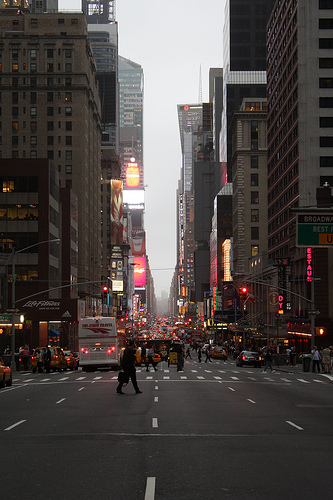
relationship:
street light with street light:
[238, 286, 247, 301] [242, 286, 248, 294]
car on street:
[233, 348, 263, 367] [3, 315, 328, 491]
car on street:
[206, 343, 228, 359] [3, 315, 328, 491]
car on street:
[29, 345, 66, 373] [3, 315, 328, 491]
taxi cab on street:
[134, 346, 161, 368] [3, 315, 328, 491]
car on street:
[189, 332, 204, 351] [3, 315, 328, 491]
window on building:
[120, 117, 135, 129] [117, 56, 144, 190]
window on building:
[123, 114, 135, 118] [117, 56, 144, 190]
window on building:
[116, 84, 120, 89] [117, 56, 144, 190]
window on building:
[116, 84, 142, 89] [117, 56, 144, 190]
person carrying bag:
[116, 340, 142, 395] [116, 371, 129, 383]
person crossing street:
[116, 340, 142, 395] [6, 340, 331, 498]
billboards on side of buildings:
[104, 178, 149, 292] [3, 13, 144, 369]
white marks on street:
[44, 372, 329, 384] [178, 323, 217, 499]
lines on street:
[2, 358, 332, 499] [3, 315, 328, 491]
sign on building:
[298, 246, 314, 281] [264, 0, 331, 325]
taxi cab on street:
[127, 342, 164, 369] [6, 340, 331, 498]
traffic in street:
[131, 316, 262, 366] [3, 315, 328, 491]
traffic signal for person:
[11, 306, 27, 330] [116, 340, 142, 395]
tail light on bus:
[108, 349, 110, 353] [77, 316, 118, 372]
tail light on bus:
[111, 345, 114, 349] [77, 316, 118, 372]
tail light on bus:
[85, 350, 88, 353] [77, 316, 118, 372]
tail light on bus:
[80, 347, 83, 350] [77, 316, 118, 372]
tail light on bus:
[94, 343, 100, 345] [77, 316, 118, 372]